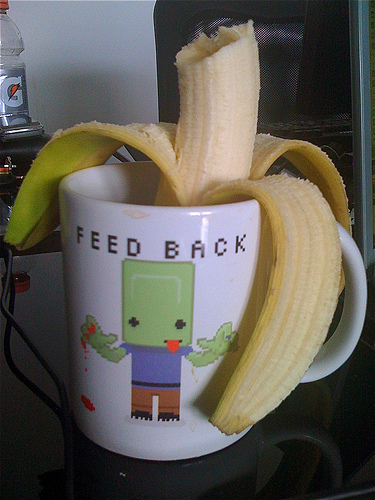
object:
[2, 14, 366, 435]
banana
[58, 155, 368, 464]
mug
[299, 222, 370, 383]
handle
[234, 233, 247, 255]
lettering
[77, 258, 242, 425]
figure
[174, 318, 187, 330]
eye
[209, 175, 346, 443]
peel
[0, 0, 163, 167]
wall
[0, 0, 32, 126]
bottle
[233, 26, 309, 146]
chair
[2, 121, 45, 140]
phone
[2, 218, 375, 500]
desk